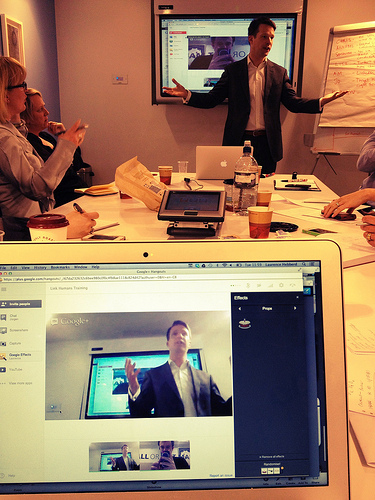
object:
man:
[173, 6, 324, 167]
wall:
[52, 4, 374, 183]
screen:
[158, 14, 300, 104]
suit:
[199, 60, 303, 158]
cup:
[26, 210, 72, 241]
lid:
[23, 212, 70, 229]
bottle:
[231, 139, 254, 209]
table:
[0, 167, 368, 498]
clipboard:
[272, 172, 322, 195]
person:
[0, 191, 102, 247]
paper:
[88, 215, 127, 241]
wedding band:
[180, 55, 321, 178]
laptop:
[195, 141, 254, 181]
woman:
[0, 52, 87, 220]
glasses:
[0, 81, 32, 96]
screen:
[161, 12, 296, 95]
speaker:
[159, 14, 347, 174]